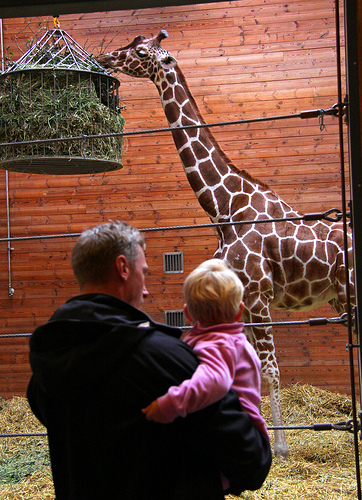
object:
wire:
[243, 315, 340, 330]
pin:
[0, 0, 362, 499]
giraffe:
[95, 32, 360, 463]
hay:
[226, 383, 357, 498]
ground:
[224, 382, 361, 498]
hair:
[176, 254, 247, 322]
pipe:
[4, 168, 14, 296]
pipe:
[1, 18, 6, 70]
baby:
[138, 255, 266, 437]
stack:
[1, 400, 48, 496]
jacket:
[25, 291, 272, 499]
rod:
[330, 99, 361, 493]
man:
[23, 217, 274, 498]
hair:
[70, 216, 149, 292]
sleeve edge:
[153, 394, 171, 426]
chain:
[3, 112, 309, 149]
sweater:
[156, 322, 267, 439]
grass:
[0, 66, 122, 157]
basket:
[1, 26, 126, 174]